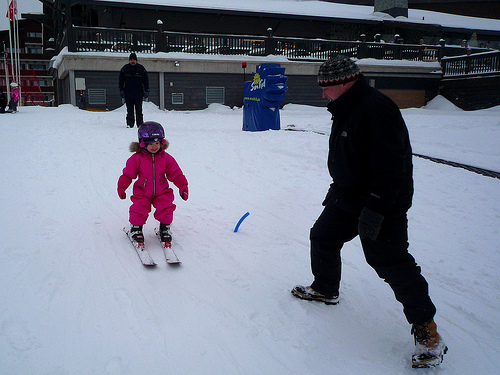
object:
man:
[291, 57, 450, 369]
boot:
[290, 286, 341, 304]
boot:
[410, 317, 449, 368]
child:
[116, 120, 190, 242]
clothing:
[117, 139, 189, 242]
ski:
[123, 225, 157, 270]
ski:
[153, 226, 179, 268]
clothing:
[118, 62, 151, 128]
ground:
[32, 209, 82, 242]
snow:
[4, 125, 85, 183]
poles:
[0, 9, 27, 105]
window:
[203, 87, 232, 109]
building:
[5, 0, 499, 113]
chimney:
[373, 0, 410, 20]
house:
[49, 6, 499, 111]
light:
[238, 57, 249, 71]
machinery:
[239, 56, 291, 133]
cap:
[127, 51, 138, 60]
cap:
[315, 52, 365, 88]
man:
[112, 49, 155, 133]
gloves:
[113, 89, 127, 104]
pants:
[122, 86, 144, 127]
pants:
[308, 185, 438, 324]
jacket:
[117, 62, 150, 99]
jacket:
[325, 74, 415, 206]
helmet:
[135, 121, 169, 148]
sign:
[244, 71, 274, 93]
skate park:
[1, 2, 500, 375]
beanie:
[316, 54, 365, 88]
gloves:
[356, 194, 385, 234]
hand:
[360, 99, 391, 245]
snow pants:
[308, 198, 437, 324]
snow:
[44, 298, 229, 362]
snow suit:
[115, 141, 190, 201]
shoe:
[157, 222, 174, 243]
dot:
[327, 60, 334, 68]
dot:
[337, 59, 344, 64]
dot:
[338, 68, 346, 74]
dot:
[343, 58, 348, 64]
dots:
[318, 69, 324, 74]